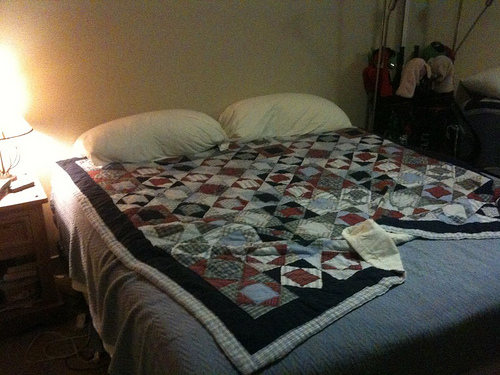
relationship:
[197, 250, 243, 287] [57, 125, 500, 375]
design on quilt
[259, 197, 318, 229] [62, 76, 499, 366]
design on quilt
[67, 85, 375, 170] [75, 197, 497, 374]
bed pillows on bed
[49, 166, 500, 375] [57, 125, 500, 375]
bedspread under quilt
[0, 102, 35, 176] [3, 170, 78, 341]
lamp on night stand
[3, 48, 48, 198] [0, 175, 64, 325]
lamp on a bed side end table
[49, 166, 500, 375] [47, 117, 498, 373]
bedspread on a bed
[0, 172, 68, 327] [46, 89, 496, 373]
end table on side of bed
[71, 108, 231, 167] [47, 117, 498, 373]
bed pillows on bed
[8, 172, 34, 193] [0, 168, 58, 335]
book on nightstand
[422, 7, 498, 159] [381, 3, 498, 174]
mirror against wall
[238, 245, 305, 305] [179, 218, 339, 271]
design on quilt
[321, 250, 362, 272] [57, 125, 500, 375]
design on quilt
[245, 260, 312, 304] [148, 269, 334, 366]
design on quilt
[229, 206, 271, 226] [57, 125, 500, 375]
design on quilt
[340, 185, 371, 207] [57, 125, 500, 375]
design on quilt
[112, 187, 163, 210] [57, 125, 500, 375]
design on quilt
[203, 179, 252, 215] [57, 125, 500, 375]
design on quilt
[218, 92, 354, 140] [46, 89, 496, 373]
pillow on bed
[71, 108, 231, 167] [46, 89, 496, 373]
bed pillows on bed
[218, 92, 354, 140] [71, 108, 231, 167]
pillow by bed pillows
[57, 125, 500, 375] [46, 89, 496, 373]
quilt on bed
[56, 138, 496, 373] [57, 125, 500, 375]
bedspread under quilt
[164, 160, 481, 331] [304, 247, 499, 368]
quilt on bed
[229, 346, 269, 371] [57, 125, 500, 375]
corner of quilt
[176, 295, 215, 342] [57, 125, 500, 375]
edge of quilt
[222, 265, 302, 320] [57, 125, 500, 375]
design on quilt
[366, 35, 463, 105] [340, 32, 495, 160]
objects in background